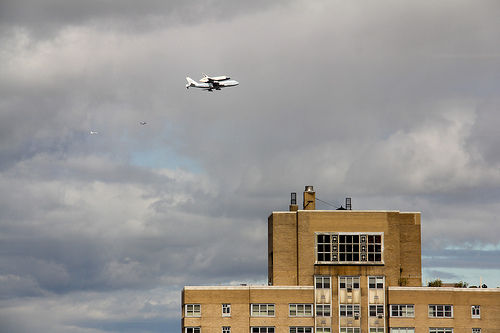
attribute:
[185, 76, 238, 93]
plane — white, flying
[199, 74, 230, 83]
shuttle — white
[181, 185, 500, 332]
building — colored, large, brown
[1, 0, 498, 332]
sky — cloudy